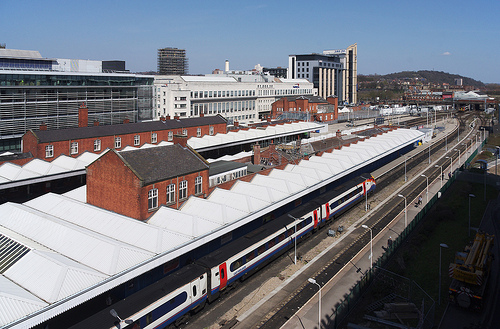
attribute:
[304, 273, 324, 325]
street light — white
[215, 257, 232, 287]
door — tall, thin, red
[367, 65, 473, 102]
mountain — sloped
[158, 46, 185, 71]
building — Round , Gray 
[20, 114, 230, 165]
building — long, red, brick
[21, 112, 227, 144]
roof — black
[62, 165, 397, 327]
train — red, white, black, and blue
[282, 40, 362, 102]
building — red , large, distant, beige, gray